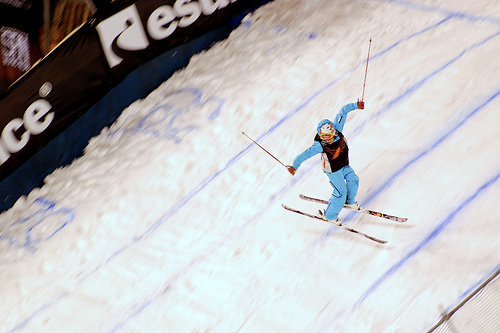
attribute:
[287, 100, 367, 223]
person — skiing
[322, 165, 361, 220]
ski pants — blue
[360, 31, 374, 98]
ski pole — red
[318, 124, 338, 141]
helmet — white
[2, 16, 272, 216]
net — black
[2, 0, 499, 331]
snow — white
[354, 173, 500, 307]
line — blue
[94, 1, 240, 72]
writing — white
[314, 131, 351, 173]
suit — black, orange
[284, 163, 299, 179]
glove — red